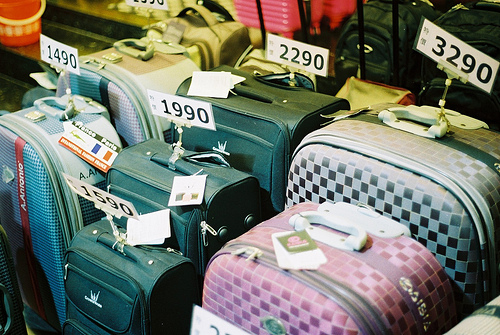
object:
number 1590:
[79, 183, 136, 220]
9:
[297, 48, 312, 68]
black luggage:
[167, 63, 355, 214]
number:
[115, 200, 138, 217]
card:
[58, 169, 142, 221]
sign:
[144, 89, 218, 134]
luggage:
[199, 200, 461, 335]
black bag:
[58, 218, 205, 334]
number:
[432, 34, 453, 59]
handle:
[376, 104, 448, 139]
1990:
[160, 97, 210, 125]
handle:
[285, 210, 368, 253]